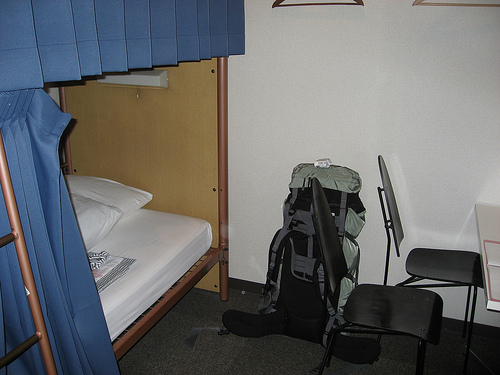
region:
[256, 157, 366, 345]
black and grey backpack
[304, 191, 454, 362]
small black plastic chair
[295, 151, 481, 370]
two black chairs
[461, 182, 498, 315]
edge of white desk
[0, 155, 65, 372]
brown wooden ladder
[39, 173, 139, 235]
white pillow on the bed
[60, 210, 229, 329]
mattress with white sheets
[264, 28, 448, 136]
empty white wall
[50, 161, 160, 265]
white pillow and white mattress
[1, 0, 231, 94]
blue pleated drapes covering bed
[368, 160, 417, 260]
a small part placed to wall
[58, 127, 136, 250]
a beautiful white pillow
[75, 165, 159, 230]
a part of white pillow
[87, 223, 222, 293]
a beautiful white bed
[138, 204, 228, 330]
a part of white bed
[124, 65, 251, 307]
a small part of wood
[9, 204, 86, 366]
a small iron stand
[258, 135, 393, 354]
a group of bags placed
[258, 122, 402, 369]
lagugage place to wall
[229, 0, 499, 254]
a beautiful white wall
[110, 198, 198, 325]
the bed is white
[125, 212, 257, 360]
the bed is white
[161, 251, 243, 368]
the bed is white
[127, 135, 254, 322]
the bed is white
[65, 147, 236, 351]
the bed is white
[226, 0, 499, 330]
the wall is eggshell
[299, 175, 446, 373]
the chair is black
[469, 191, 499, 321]
the table is white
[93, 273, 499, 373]
the carpet is grey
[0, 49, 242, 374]
the bed is brown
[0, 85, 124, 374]
the curtain is blue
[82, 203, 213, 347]
the sheet is white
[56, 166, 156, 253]
the pillow is white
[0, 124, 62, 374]
the ladder is brown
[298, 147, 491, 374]
two chairs side by side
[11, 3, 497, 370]
a bedroom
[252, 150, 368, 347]
a packsack on the floor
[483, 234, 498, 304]
an opened notebook on a table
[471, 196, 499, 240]
a white table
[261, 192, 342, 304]
straps on a packsack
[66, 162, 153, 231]
white pillows on a bed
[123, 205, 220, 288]
white sheet on a mattress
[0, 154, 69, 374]
a brown bed ladder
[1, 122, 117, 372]
blue drapes